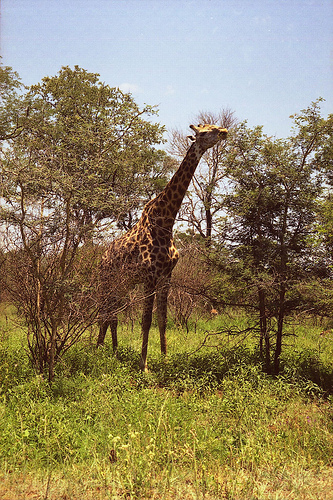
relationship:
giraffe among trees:
[92, 104, 235, 364] [3, 56, 330, 389]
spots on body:
[67, 151, 224, 312] [90, 201, 182, 292]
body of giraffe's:
[90, 201, 182, 292] [86, 110, 236, 374]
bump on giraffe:
[166, 244, 185, 269] [70, 118, 230, 382]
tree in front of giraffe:
[0, 62, 172, 391] [90, 122, 235, 380]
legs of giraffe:
[139, 276, 170, 373] [90, 122, 235, 380]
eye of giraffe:
[199, 129, 207, 138] [90, 122, 235, 380]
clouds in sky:
[0, 0, 333, 107] [130, 10, 302, 98]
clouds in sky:
[113, 73, 230, 106] [30, 23, 314, 116]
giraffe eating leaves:
[90, 122, 235, 380] [231, 131, 246, 141]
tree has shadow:
[195, 95, 322, 374] [180, 329, 326, 387]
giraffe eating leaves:
[90, 122, 235, 380] [208, 119, 269, 181]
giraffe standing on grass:
[90, 122, 235, 380] [2, 287, 331, 500]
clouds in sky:
[0, 0, 333, 107] [0, 0, 331, 273]